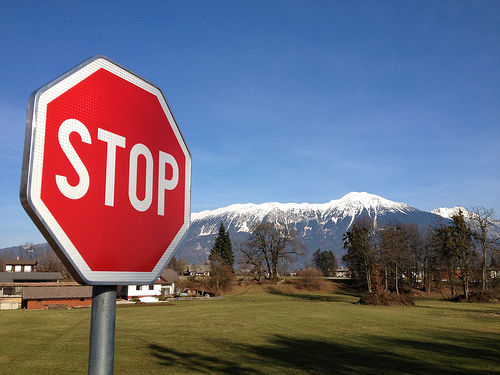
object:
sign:
[18, 53, 194, 289]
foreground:
[0, 292, 500, 375]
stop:
[54, 117, 180, 216]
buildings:
[21, 285, 96, 310]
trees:
[461, 204, 499, 303]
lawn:
[0, 293, 500, 374]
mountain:
[1, 190, 500, 274]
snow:
[191, 191, 410, 238]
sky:
[0, 0, 499, 249]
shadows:
[145, 341, 266, 375]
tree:
[208, 222, 236, 298]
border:
[18, 93, 38, 201]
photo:
[0, 0, 500, 374]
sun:
[1, 305, 342, 341]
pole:
[86, 285, 119, 375]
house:
[120, 268, 179, 302]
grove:
[340, 205, 500, 307]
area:
[295, 251, 499, 289]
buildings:
[430, 263, 472, 283]